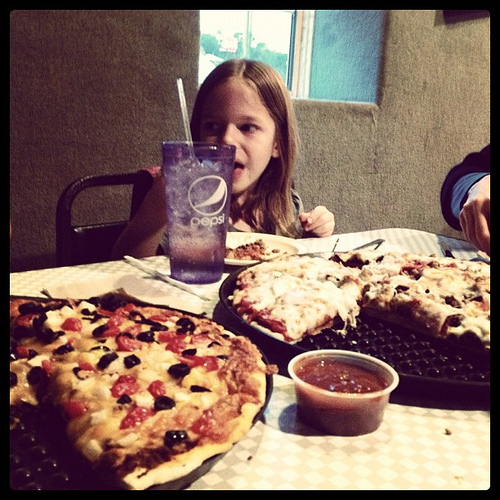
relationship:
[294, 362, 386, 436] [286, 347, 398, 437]
sauce in a container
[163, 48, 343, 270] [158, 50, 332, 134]
girl with hair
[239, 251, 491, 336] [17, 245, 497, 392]
pizza on table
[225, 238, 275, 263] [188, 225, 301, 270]
slice on plate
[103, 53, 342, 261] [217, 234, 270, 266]
girl eating pizza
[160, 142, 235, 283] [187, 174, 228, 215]
glass with logo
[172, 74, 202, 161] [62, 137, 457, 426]
drinking straw on a table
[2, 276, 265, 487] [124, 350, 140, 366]
pizza pie with olive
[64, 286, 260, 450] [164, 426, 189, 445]
pizza with olive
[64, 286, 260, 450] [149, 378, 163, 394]
pizza with tomatoe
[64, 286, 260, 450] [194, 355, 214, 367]
pizza with tomatoe